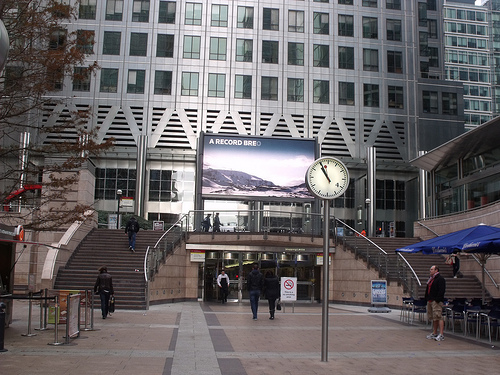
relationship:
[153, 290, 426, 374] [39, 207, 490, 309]
walkway up to stairs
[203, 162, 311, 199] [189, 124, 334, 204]
mountains on billboard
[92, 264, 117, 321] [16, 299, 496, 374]
people walking by place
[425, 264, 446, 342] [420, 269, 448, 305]
man in shirt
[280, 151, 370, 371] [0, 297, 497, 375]
clock in middle of ground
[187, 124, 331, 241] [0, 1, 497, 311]
sign in front of building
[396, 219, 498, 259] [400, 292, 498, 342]
blue umbrella over chairs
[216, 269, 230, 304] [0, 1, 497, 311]
people coming out of building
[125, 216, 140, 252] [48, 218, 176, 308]
person walking up stairs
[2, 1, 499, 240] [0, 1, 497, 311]
windows on building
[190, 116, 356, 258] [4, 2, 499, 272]
billboard on building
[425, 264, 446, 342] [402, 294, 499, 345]
man standing beside chairs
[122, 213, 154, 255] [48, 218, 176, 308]
person walking up stairs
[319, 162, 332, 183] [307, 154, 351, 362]
hand on clock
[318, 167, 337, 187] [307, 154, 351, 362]
hand on clock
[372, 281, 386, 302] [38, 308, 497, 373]
logo on ground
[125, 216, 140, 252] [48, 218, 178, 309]
person walking up staircase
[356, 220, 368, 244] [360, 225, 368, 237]
person wearing orange jacket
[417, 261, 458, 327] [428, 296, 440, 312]
man with hands in pocket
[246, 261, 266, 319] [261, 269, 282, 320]
people closely walking with people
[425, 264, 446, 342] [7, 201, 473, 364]
man in area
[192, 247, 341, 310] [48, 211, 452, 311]
door beneath stairway